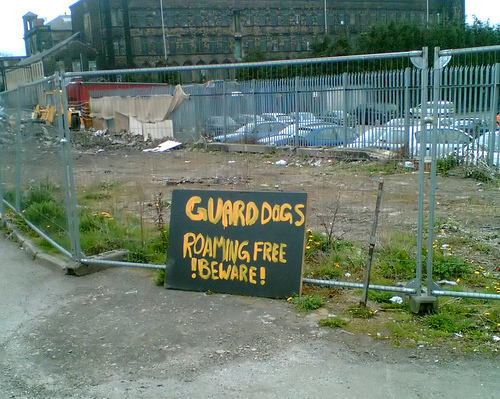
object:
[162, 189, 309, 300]
sign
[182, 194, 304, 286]
writing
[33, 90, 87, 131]
machine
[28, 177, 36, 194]
flower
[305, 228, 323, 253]
flower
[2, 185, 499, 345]
grass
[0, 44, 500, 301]
fence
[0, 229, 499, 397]
cement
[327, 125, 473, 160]
car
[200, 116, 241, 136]
car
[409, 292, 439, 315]
cinder blocks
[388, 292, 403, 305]
trash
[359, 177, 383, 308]
pole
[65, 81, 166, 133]
building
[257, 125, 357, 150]
cars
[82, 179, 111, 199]
patch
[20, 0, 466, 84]
building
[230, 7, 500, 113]
trees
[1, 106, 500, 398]
field